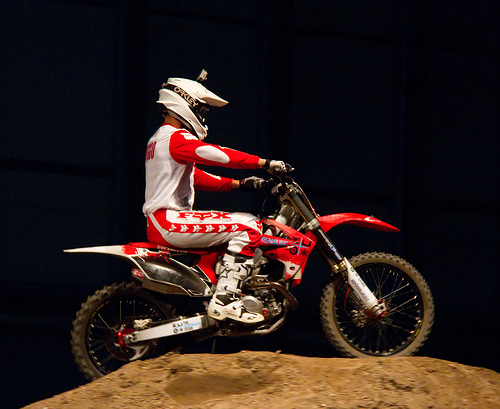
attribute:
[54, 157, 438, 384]
motorcycle — white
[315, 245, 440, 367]
tire — black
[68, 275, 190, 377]
tire — black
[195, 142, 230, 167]
patch — white, elbow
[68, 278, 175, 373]
tire — rear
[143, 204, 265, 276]
pants — white, red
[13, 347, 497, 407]
hill — dirt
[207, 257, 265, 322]
boot — white, black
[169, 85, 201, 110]
logo — OAKLEY, printed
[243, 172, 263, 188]
glove — white, black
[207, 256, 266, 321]
boots — heavy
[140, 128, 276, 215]
shirt — red, white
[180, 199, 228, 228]
word — fox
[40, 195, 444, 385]
bike — dirt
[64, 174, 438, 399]
bike — dirt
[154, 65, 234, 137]
helmet — white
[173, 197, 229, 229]
word — FOX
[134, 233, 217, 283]
seat — red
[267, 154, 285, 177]
glove — black